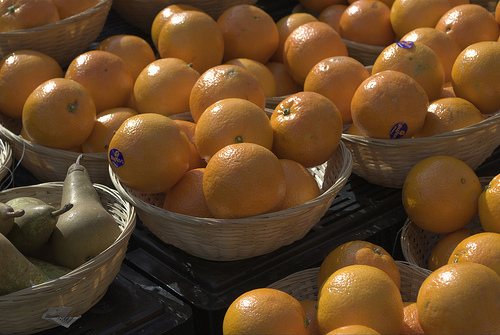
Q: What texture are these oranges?
A: Bumpy.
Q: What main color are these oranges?
A: Orange.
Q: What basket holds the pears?
A: The tan one.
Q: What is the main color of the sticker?
A: Blue.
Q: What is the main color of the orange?
A: Orange.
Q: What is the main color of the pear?
A: Green.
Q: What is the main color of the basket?
A: Brown.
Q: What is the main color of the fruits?
A: Orange.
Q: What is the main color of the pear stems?
A: Brown.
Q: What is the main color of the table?
A: Brown.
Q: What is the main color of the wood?
A: Tan.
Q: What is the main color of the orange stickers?
A: Blue.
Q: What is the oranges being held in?
A: Bowl.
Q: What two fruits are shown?
A: Oranges and pears.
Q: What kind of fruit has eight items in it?
A: Oranges.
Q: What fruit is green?
A: Pears.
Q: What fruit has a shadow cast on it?
A: Oranges.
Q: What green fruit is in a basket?
A: Pears.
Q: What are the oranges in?
A: Baskets.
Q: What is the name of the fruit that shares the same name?
A: Orange.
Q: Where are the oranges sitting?
A: Basket.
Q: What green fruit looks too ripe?
A: Pears.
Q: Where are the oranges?
A: In the bowls.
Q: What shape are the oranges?
A: Spheres.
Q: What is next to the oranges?
A: Pears.